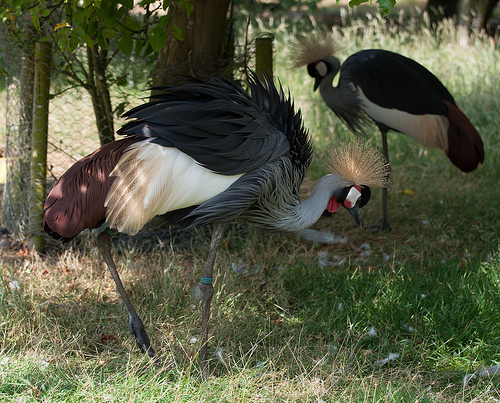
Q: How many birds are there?
A: Two.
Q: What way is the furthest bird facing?
A: Left.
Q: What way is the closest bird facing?
A: Right.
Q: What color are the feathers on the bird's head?
A: Tan.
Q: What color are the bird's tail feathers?
A: Brown.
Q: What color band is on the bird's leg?
A: Green.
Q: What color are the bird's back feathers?
A: Black.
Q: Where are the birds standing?
A: In grass.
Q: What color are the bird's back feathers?
A: Maroon.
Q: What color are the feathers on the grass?
A: White.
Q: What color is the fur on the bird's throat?
A: Gray.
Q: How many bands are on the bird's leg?
A: One.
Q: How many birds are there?
A: Two.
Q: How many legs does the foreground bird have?
A: Two.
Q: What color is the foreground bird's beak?
A: Black.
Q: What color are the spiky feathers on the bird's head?
A: Beige.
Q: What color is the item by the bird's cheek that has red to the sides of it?
A: White.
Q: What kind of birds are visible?
A: Peacocks.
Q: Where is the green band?
A: Around the first birds leg.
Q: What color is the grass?
A: Green.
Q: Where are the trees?
A: Behind the birds.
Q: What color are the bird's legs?
A: Brown.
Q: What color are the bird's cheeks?
A: Red and white.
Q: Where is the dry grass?
A: Around the trees.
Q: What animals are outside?
A: Birds.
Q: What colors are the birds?
A: Black and white.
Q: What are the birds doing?
A: Grazing.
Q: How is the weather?
A: Sunny.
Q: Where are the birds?
A: In the woods.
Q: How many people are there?
A: None.